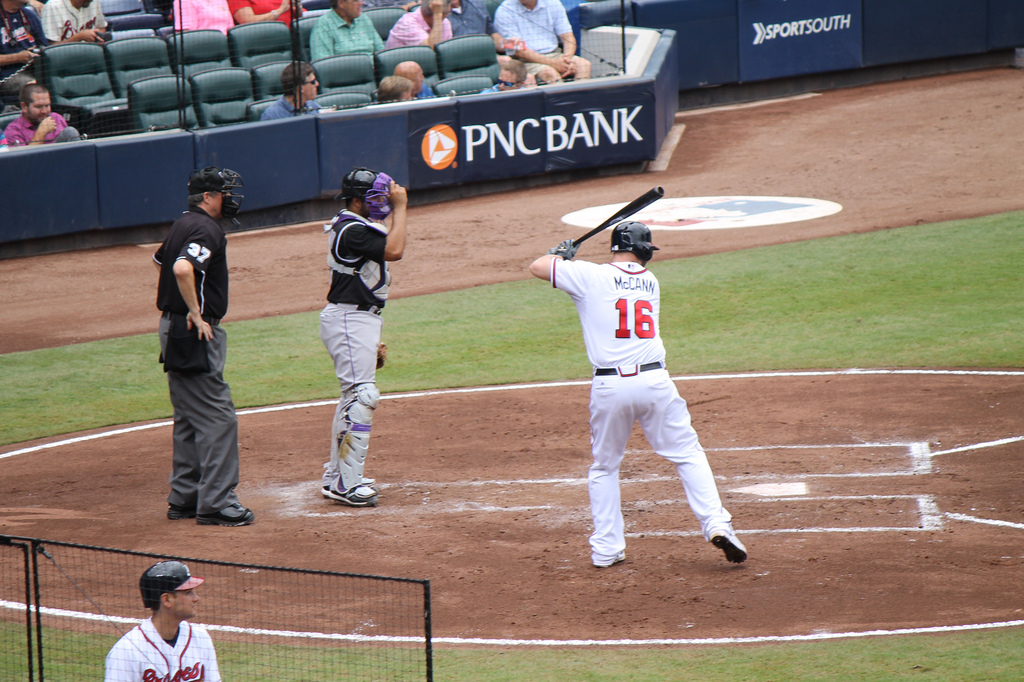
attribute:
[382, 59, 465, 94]
person — sitting down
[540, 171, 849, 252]
emblems — team's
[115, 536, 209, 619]
head — man's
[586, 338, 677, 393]
waist — man's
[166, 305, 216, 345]
hands — man's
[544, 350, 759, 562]
pants — white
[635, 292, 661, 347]
number — 6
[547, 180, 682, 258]
bat — black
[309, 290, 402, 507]
pants — grey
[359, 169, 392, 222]
mask — purple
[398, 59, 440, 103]
person — sitting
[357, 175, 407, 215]
face mask — purple  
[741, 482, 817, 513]
home plate — white 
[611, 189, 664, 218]
bat — long, thin, black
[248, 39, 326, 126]
person — baseball game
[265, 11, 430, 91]
person — baseball game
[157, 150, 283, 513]
umpire — black shirt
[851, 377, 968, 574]
dirt — White lines 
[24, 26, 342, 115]
seats — Four empty green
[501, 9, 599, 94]
person — blue shirt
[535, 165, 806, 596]
player — baseball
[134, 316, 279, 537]
pants — gray , pair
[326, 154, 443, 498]
catcher — baseball 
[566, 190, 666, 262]
bat — black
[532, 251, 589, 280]
gloves — batting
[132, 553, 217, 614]
helmet — black, red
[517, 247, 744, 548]
man — standing